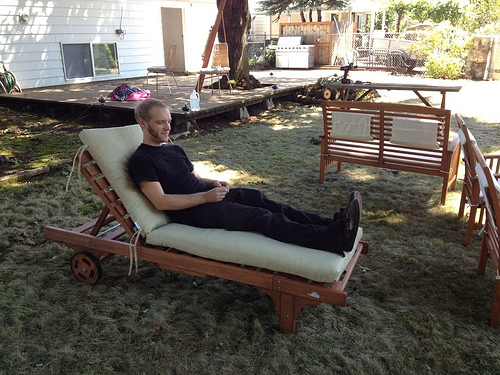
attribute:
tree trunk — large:
[214, 1, 284, 93]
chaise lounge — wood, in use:
[33, 114, 367, 337]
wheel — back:
[66, 251, 101, 286]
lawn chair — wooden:
[33, 120, 375, 325]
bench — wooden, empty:
[319, 99, 463, 205]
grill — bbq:
[272, 36, 316, 69]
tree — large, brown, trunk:
[191, 34, 311, 97]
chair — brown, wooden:
[42, 146, 374, 333]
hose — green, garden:
[1, 59, 17, 96]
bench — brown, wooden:
[312, 90, 464, 209]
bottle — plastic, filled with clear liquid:
[184, 86, 206, 118]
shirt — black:
[128, 142, 204, 204]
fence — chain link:
[270, 15, 478, 72]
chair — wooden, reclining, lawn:
[43, 92, 419, 328]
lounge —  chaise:
[46, 118, 376, 334]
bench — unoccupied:
[315, 96, 465, 199]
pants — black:
[171, 183, 365, 262]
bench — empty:
[304, 95, 466, 206]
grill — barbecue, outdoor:
[271, 35, 316, 67]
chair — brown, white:
[127, 45, 203, 90]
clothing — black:
[131, 139, 361, 257]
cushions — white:
[329, 103, 459, 165]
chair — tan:
[40, 124, 378, 328]